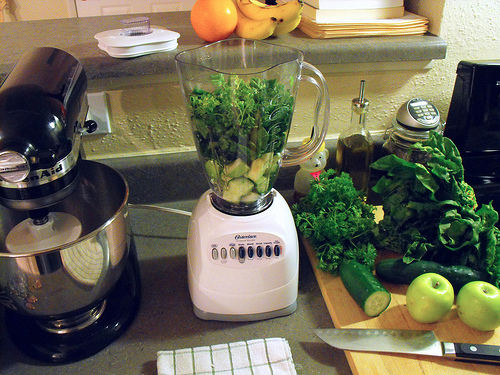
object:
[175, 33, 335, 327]
blender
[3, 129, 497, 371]
counter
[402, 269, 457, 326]
apples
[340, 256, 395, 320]
cucumber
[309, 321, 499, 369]
knife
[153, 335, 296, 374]
cloth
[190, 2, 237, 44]
orange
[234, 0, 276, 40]
bananas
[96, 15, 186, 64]
lid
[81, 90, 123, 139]
outlet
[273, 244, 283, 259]
button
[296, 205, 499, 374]
board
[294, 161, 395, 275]
leaves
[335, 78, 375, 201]
bottle